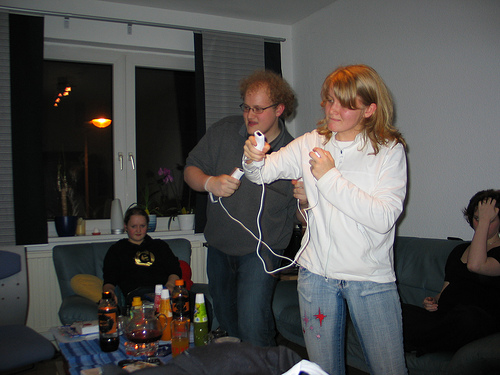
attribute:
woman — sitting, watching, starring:
[102, 206, 211, 323]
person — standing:
[242, 63, 410, 374]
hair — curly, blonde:
[237, 70, 300, 124]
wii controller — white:
[217, 165, 311, 236]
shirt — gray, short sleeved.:
[184, 115, 297, 255]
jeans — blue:
[207, 248, 284, 352]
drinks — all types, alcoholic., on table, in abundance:
[96, 278, 209, 360]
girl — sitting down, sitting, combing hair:
[402, 189, 499, 355]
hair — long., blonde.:
[316, 63, 408, 155]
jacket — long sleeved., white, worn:
[243, 125, 408, 282]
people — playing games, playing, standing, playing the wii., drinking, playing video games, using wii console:
[181, 66, 410, 374]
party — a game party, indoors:
[1, 2, 499, 373]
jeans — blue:
[294, 262, 410, 375]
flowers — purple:
[156, 161, 180, 216]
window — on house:
[42, 38, 204, 241]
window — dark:
[39, 58, 118, 243]